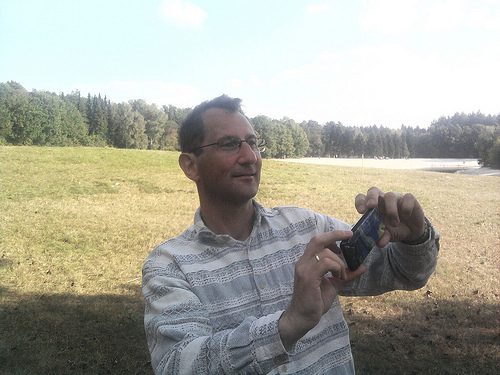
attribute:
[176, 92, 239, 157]
hair — brown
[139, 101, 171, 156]
tall tree — bright green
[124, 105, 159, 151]
tall tree — bright green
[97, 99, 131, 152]
tall tree — bright green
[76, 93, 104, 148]
tall tree — bright green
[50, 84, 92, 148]
tall tree — bright green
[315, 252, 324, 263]
ring — silver colored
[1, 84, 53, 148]
tree — bright green, tall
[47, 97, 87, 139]
tree — tall, bright green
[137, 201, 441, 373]
shirt — gray and white, striped, long sleeve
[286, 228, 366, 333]
hand — man's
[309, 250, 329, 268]
ring — metal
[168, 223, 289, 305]
shirt — white, grey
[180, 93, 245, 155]
hair — brown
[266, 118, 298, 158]
tree — bright green, tall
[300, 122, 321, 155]
tree — tall, bright green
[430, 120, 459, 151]
tree — bright green, tall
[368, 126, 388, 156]
tree — tall, bright green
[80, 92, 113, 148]
tree — tall, bright green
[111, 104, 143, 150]
tree — bright green, tall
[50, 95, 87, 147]
tree — tall, bright green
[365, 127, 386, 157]
tree — bright green, tall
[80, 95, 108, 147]
tree — bright green, tall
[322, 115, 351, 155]
tree — tall, bright green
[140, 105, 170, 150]
tree — bright green, tall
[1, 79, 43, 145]
tree — tall, bright green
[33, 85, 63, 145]
tree — bright green, tall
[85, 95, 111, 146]
tree — tall, bright green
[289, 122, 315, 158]
tree — bright green, tall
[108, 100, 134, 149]
tree — tall, bright green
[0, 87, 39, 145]
tree — bright green, tall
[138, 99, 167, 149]
tree — tall, bright green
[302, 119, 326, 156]
tree — bright green, tall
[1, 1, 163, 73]
sky — blue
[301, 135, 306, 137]
leaf — green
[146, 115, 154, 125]
leaf — green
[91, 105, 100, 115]
leaf — green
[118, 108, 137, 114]
leaf — green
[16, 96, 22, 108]
leaf — green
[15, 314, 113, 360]
grass — green